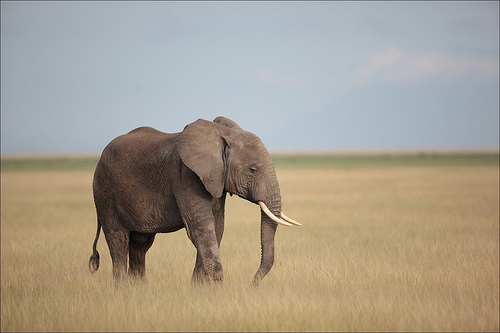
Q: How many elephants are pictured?
A: One.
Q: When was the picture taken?
A: Daytime.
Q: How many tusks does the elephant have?
A: Two.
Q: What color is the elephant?
A: Grey.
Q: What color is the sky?
A: Blue.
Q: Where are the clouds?
A: In the sky.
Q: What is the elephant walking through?
A: Tall grass.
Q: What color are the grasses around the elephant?
A: Yellow.